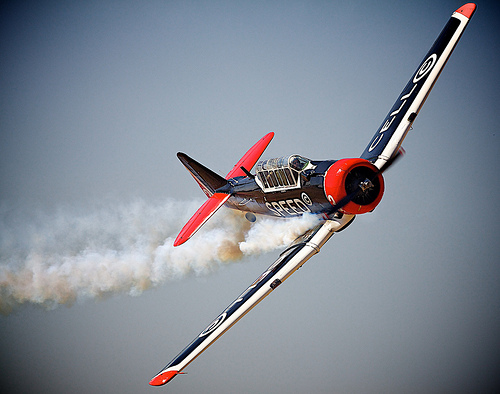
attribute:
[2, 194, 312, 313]
smoke — grey, white, brown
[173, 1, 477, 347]
plane — patriotic, clear, black, white, red, in sight, flying, performing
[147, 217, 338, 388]
wing — long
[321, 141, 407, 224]
propeller — black, moving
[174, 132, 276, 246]
tail — red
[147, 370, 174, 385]
wing tip — red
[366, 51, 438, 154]
print — white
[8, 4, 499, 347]
sky — blue, clear, cloudless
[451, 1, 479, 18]
wing tip — red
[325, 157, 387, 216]
nose — red